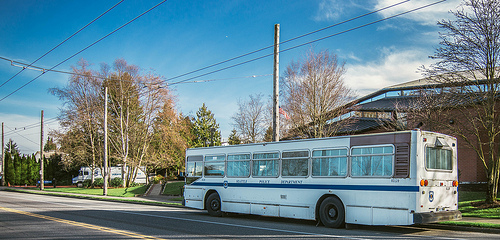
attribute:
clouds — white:
[289, 0, 496, 110]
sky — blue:
[2, 0, 498, 156]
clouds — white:
[0, 6, 498, 155]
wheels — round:
[204, 193, 347, 227]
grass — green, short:
[424, 182, 494, 229]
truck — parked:
[69, 162, 147, 187]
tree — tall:
[189, 104, 219, 145]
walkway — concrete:
[142, 177, 169, 198]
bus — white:
[186, 130, 456, 230]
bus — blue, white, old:
[180, 125, 470, 234]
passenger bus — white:
[177, 124, 470, 233]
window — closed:
[419, 144, 458, 171]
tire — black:
[317, 194, 349, 232]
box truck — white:
[72, 160, 145, 188]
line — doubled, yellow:
[4, 202, 141, 238]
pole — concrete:
[270, 19, 286, 141]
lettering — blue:
[233, 174, 304, 190]